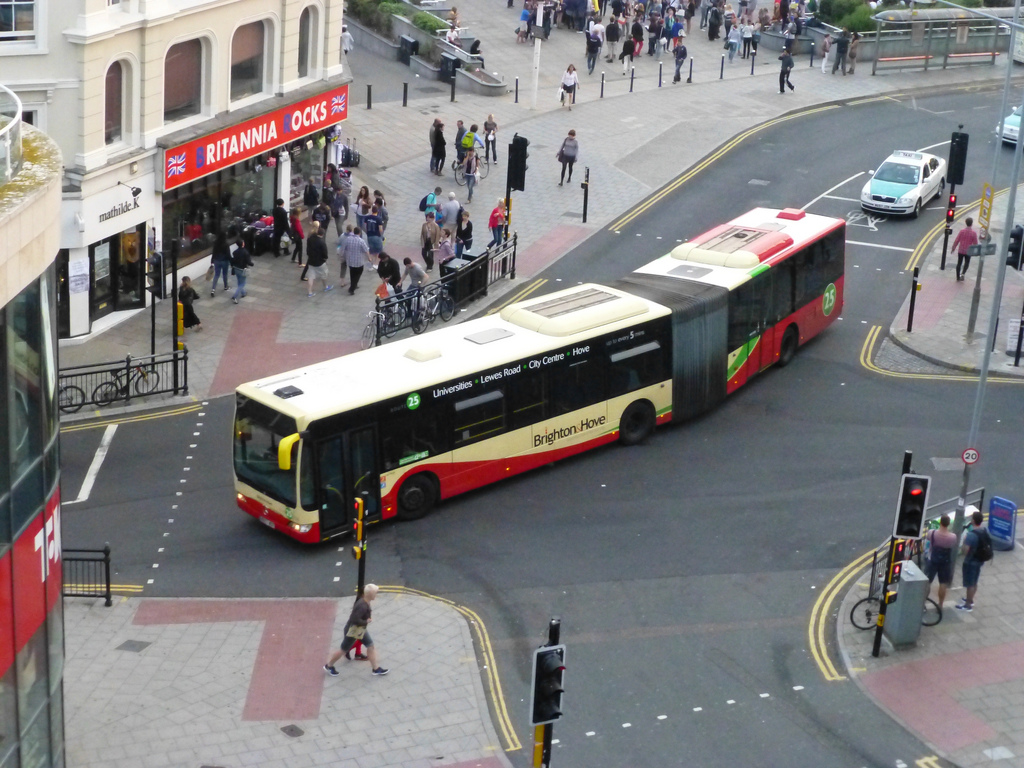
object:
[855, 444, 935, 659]
pole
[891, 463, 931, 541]
lights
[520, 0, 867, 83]
crowd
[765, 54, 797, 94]
people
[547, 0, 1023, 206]
street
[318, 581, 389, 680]
person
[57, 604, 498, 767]
sidewalk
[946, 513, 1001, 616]
person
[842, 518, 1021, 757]
sidewalk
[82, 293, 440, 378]
sidewalk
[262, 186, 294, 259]
person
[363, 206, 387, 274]
person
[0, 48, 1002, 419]
sidewalk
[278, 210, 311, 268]
people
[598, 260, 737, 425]
accordion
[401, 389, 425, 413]
circle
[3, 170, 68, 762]
wall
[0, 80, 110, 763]
building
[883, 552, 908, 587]
light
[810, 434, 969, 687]
corner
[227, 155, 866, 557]
bus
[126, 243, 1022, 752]
street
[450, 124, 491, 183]
person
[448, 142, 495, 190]
bike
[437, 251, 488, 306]
trashcans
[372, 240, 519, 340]
fence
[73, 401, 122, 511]
line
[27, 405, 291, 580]
road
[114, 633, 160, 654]
bricks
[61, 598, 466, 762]
sidewalk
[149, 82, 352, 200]
red sign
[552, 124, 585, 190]
person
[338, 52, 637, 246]
sidewalk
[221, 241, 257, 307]
people